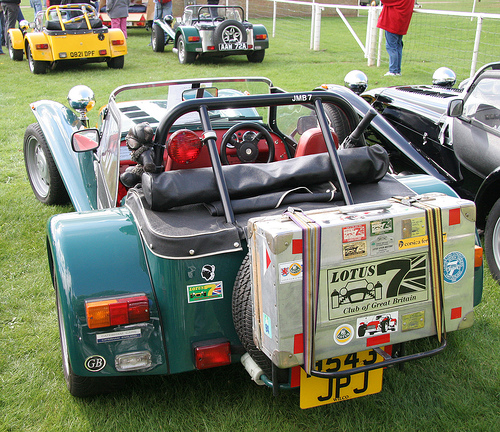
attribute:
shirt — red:
[374, 0, 415, 36]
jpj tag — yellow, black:
[289, 350, 396, 407]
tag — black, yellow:
[305, 360, 390, 410]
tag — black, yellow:
[296, 344, 386, 412]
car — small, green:
[21, 91, 484, 411]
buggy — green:
[25, 52, 489, 397]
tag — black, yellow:
[308, 352, 396, 401]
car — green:
[15, 58, 490, 410]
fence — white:
[421, 12, 483, 62]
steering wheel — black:
[218, 121, 273, 164]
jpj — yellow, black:
[286, 344, 405, 417]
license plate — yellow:
[303, 343, 394, 406]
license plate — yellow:
[66, 48, 100, 57]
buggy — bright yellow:
[4, 1, 127, 72]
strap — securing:
[286, 195, 446, 374]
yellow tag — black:
[244, 360, 430, 430]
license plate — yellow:
[297, 364, 385, 404]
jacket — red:
[375, 0, 411, 35]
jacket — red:
[377, 3, 414, 26]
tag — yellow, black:
[345, 53, 465, 92]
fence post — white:
[474, 21, 478, 75]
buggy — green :
[7, 37, 467, 392]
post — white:
[263, 2, 278, 37]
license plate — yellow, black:
[298, 348, 389, 408]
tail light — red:
[190, 334, 229, 370]